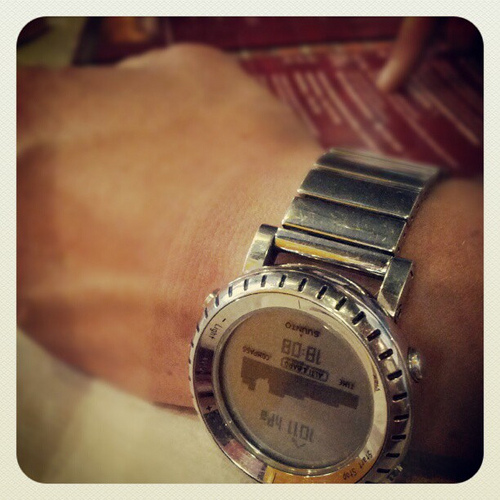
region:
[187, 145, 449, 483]
the shiny silver watch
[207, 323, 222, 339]
the word "Light" on the watch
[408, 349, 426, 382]
the button the watch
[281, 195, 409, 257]
the link on the watch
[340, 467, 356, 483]
the word "Stop" on the watch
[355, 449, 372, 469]
the word "Start" on the watch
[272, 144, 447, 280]
the band on the watch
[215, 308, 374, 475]
the face of the digital watch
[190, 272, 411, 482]
the black groove lines on the watch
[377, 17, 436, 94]
the blurry finger in the back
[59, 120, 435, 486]
Man is wearing watch.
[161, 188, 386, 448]
watch is silver color.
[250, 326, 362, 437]
Letters inside are black color.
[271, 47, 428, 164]
Paper is red color.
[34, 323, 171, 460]
Man is having the hand in the table.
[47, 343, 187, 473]
Table is white color.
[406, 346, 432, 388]
Screw is silver color.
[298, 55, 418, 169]
Letters are white color.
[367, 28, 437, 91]
One finger is touching the paper.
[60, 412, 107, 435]
this is a table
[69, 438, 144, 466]
the table is wooden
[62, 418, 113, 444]
the table is white in color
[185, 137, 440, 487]
this is a watch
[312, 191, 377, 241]
the watch is metallic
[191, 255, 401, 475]
the screen is round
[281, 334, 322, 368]
these are some digits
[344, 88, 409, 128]
the area is red in color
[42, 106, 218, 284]
this is a hand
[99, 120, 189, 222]
the skin is light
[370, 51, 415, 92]
leg of a brown chair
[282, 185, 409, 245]
silver links of a watch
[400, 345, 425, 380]
push button on watch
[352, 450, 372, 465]
start engraving on watch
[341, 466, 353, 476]
stop engraving on watch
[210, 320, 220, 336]
light engraving on ring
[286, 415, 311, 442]
digital time on watch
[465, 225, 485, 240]
fereckle on skin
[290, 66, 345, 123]
lines on red flooring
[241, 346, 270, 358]
digital compass on watch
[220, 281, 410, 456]
silver rim on watch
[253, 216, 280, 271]
silver bracket on watch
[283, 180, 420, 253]
silver link on watch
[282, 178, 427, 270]
silver band on watch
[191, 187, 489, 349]
arm wearing silver watch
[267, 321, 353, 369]
black letters on watch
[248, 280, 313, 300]
black indents on watch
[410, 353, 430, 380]
silver knob on watch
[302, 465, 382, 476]
gold tent on watch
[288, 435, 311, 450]
black arrow on watch